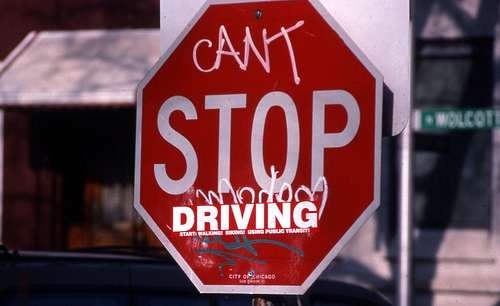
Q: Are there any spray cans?
A: No, there are no spray cans.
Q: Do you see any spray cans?
A: No, there are no spray cans.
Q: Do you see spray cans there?
A: No, there are no spray cans.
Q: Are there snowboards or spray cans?
A: No, there are no spray cans or snowboards.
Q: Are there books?
A: No, there are no books.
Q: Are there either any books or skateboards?
A: No, there are no books or skateboards.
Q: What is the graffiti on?
A: The graffiti is on the poster.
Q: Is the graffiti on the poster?
A: Yes, the graffiti is on the poster.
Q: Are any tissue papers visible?
A: No, there are no tissue papers.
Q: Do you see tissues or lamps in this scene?
A: No, there are no tissues or lamps.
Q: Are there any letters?
A: Yes, there are letters.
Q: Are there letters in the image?
A: Yes, there are letters.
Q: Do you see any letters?
A: Yes, there are letters.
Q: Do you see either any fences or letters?
A: Yes, there are letters.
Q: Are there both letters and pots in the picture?
A: No, there are letters but no pots.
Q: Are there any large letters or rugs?
A: Yes, there are large letters.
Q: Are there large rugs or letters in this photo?
A: Yes, there are large letters.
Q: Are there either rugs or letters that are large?
A: Yes, the letters are large.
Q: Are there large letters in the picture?
A: Yes, there are large letters.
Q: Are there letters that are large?
A: Yes, there are letters that are large.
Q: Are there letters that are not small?
A: Yes, there are large letters.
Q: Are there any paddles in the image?
A: No, there are no paddles.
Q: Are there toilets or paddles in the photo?
A: No, there are no paddles or toilets.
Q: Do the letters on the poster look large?
A: Yes, the letters are large.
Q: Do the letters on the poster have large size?
A: Yes, the letters are large.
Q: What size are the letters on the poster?
A: The letters are large.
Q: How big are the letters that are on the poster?
A: The letters are large.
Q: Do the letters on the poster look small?
A: No, the letters are large.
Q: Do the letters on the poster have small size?
A: No, the letters are large.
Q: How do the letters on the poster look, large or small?
A: The letters are large.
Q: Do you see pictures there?
A: No, there are no pictures.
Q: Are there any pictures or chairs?
A: No, there are no pictures or chairs.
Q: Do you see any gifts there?
A: No, there are no gifts.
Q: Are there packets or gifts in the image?
A: No, there are no gifts or packets.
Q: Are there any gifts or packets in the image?
A: No, there are no gifts or packets.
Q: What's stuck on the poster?
A: The sticker is stuck on the poster.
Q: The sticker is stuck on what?
A: The sticker is stuck on the poster.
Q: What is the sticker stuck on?
A: The sticker is stuck on the poster.